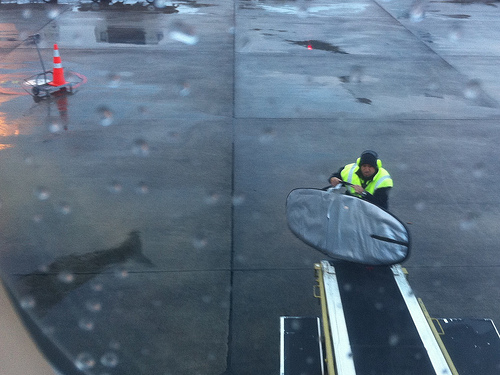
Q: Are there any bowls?
A: No, there are no bowls.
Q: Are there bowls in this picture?
A: No, there are no bowls.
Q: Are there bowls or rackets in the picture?
A: No, there are no bowls or rackets.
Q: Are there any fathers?
A: No, there are no fathers.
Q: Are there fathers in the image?
A: No, there are no fathers.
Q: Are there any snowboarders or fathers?
A: No, there are no fathers or snowboarders.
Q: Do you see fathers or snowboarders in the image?
A: No, there are no fathers or snowboarders.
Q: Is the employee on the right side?
A: Yes, the employee is on the right of the image.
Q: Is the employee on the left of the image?
A: No, the employee is on the right of the image.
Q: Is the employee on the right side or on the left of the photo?
A: The employee is on the right of the image.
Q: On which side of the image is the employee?
A: The employee is on the right of the image.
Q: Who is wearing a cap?
A: The employee is wearing a cap.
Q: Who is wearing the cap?
A: The employee is wearing a cap.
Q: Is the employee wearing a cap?
A: Yes, the employee is wearing a cap.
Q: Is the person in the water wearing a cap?
A: Yes, the employee is wearing a cap.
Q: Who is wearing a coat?
A: The employee is wearing a coat.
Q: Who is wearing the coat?
A: The employee is wearing a coat.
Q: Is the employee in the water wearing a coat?
A: Yes, the employee is wearing a coat.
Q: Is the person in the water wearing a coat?
A: Yes, the employee is wearing a coat.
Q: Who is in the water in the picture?
A: The employee is in the water.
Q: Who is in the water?
A: The employee is in the water.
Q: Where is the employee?
A: The employee is in the water.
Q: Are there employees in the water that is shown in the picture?
A: Yes, there is an employee in the water.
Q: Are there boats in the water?
A: No, there is an employee in the water.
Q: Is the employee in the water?
A: Yes, the employee is in the water.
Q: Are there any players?
A: No, there are no players.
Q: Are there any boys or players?
A: No, there are no players or boys.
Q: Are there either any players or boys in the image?
A: No, there are no players or boys.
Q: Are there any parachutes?
A: No, there are no parachutes.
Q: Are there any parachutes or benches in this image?
A: No, there are no parachutes or benches.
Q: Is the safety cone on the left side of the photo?
A: Yes, the safety cone is on the left of the image.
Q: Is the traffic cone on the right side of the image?
A: No, the traffic cone is on the left of the image.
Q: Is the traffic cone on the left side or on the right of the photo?
A: The traffic cone is on the left of the image.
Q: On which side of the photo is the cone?
A: The cone is on the left of the image.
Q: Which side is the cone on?
A: The cone is on the left of the image.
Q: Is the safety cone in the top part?
A: Yes, the safety cone is in the top of the image.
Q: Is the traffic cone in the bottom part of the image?
A: No, the traffic cone is in the top of the image.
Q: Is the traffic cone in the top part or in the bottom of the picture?
A: The traffic cone is in the top of the image.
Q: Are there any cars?
A: No, there are no cars.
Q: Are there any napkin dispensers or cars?
A: No, there are no cars or napkin dispensers.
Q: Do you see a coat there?
A: Yes, there is a coat.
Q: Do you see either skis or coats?
A: Yes, there is a coat.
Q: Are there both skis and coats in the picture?
A: No, there is a coat but no skis.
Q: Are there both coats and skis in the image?
A: No, there is a coat but no skis.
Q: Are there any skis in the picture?
A: No, there are no skis.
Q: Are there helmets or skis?
A: No, there are no skis or helmets.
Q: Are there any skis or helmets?
A: No, there are no skis or helmets.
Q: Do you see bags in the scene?
A: Yes, there is a bag.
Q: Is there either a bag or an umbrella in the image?
A: Yes, there is a bag.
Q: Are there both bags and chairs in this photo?
A: No, there is a bag but no chairs.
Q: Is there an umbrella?
A: No, there are no umbrellas.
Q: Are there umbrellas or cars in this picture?
A: No, there are no umbrellas or cars.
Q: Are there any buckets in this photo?
A: No, there are no buckets.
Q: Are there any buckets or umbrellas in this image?
A: No, there are no buckets or umbrellas.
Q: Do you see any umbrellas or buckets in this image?
A: No, there are no buckets or umbrellas.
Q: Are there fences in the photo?
A: No, there are no fences.